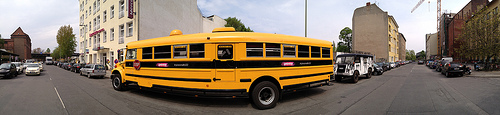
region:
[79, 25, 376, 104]
a yellow and black school bus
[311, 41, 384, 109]
a white jeep parked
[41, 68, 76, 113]
white stripe on the road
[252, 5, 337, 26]
white clouds in the blue sky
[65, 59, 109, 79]
a silver van parked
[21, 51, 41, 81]
white car driving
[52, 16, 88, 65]
green tree next to a building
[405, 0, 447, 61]
red crane in the sky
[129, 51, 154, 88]
red stop sign on the bus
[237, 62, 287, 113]
black rubber bus tire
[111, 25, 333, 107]
long yellow school bus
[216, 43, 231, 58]
window on school bus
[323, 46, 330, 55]
window on school bus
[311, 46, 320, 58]
window on school bus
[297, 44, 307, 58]
window on school bus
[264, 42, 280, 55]
window on school bus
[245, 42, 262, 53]
window on school bus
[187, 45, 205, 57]
window on school bus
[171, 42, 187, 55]
window on school bus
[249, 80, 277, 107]
tire on school bus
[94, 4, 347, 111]
a bus on the road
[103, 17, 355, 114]
a yellow bus on the road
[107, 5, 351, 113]
a school bus on the road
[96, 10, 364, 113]
a yellow school bus on th eroad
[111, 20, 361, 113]
a bus on the street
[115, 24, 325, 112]
a yellow bus on the street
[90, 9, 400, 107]
a school bus on the street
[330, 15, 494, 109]
vehicles parked on the side of road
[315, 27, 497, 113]
vehicles parked on the road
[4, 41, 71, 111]
cars driving on the road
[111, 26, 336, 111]
school bus is yellow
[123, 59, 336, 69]
large black stripe on bus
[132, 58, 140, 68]
stop sign is red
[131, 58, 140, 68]
stop sign on bus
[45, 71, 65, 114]
white stripe is faded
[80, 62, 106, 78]
gray minivan is parked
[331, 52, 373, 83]
white vehicle is all-terrain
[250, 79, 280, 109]
wheel at rear of bus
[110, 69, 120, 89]
wheel at front of bus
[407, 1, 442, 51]
crane is large and tall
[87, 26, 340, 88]
yellow bus on road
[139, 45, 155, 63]
window on school bus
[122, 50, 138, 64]
window on school bus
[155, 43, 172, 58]
window on school bus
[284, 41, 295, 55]
window on school bus